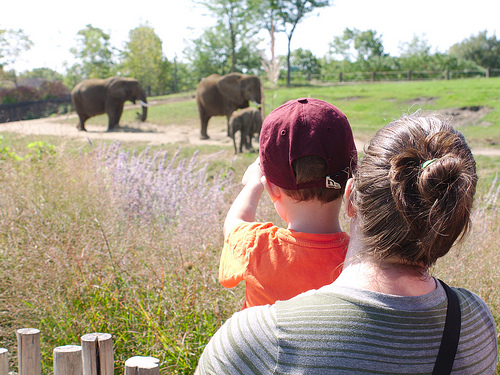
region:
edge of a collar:
[389, 290, 404, 309]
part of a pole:
[133, 360, 144, 373]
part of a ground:
[180, 240, 216, 310]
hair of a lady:
[366, 195, 401, 270]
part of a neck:
[311, 193, 336, 245]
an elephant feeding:
[49, 68, 153, 140]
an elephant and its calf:
[193, 59, 268, 146]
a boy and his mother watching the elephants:
[220, 105, 499, 373]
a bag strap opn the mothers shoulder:
[426, 256, 475, 373]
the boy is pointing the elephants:
[209, 98, 361, 290]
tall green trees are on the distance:
[216, 7, 318, 69]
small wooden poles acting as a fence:
[31, 325, 150, 373]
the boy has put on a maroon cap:
[251, 88, 358, 205]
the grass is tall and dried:
[0, 154, 198, 326]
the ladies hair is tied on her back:
[341, 81, 498, 312]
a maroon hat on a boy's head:
[258, 96, 359, 190]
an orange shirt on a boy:
[217, 221, 349, 310]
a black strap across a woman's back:
[428, 279, 467, 374]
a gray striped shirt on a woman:
[193, 277, 498, 373]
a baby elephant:
[223, 102, 263, 154]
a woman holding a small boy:
[190, 95, 495, 370]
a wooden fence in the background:
[280, 65, 497, 83]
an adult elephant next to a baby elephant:
[193, 68, 265, 141]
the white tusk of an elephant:
[136, 97, 155, 106]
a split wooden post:
[80, 330, 117, 374]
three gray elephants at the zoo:
[46, 44, 269, 164]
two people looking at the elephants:
[186, 78, 498, 368]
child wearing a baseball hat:
[255, 90, 367, 215]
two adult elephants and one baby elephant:
[82, 61, 269, 161]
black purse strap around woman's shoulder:
[417, 276, 475, 367]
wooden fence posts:
[7, 310, 169, 370]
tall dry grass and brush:
[37, 143, 214, 256]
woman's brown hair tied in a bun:
[371, 110, 481, 255]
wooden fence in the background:
[352, 55, 494, 83]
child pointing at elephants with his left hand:
[212, 140, 292, 270]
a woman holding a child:
[192, 125, 495, 374]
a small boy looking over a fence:
[210, 94, 363, 325]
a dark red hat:
[237, 80, 362, 197]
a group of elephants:
[74, 62, 292, 169]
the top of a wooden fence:
[1, 326, 176, 373]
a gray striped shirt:
[187, 287, 494, 373]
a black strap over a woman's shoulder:
[399, 268, 493, 373]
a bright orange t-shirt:
[215, 217, 355, 317]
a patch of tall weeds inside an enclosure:
[12, 142, 497, 368]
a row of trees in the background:
[4, 30, 496, 96]